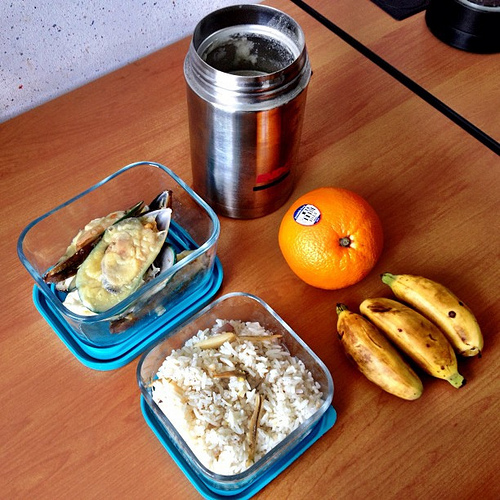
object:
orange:
[276, 185, 384, 294]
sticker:
[289, 201, 325, 228]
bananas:
[332, 303, 424, 401]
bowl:
[136, 286, 338, 492]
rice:
[172, 348, 285, 433]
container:
[181, 2, 309, 220]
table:
[1, 1, 498, 500]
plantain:
[358, 295, 467, 390]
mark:
[365, 301, 393, 313]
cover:
[30, 219, 225, 372]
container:
[17, 159, 223, 347]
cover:
[139, 370, 340, 499]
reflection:
[208, 70, 242, 221]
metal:
[184, 2, 313, 223]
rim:
[139, 290, 335, 491]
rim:
[18, 156, 220, 322]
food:
[71, 213, 180, 315]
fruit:
[276, 183, 387, 291]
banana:
[379, 270, 485, 358]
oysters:
[73, 213, 175, 318]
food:
[157, 328, 283, 447]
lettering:
[252, 165, 289, 183]